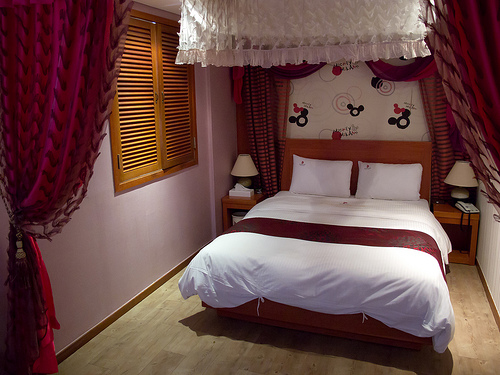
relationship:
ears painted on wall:
[386, 110, 413, 125] [225, 52, 476, 262]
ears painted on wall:
[287, 107, 312, 122] [225, 52, 476, 262]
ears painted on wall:
[344, 100, 364, 110] [225, 52, 476, 262]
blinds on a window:
[116, 18, 192, 178] [71, 14, 229, 235]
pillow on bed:
[293, 155, 351, 196] [152, 134, 466, 375]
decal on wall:
[348, 99, 365, 116] [108, 212, 198, 246]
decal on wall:
[287, 102, 312, 127] [244, 61, 471, 144]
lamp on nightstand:
[443, 160, 480, 201] [429, 201, 483, 265]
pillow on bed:
[354, 160, 423, 200] [179, 137, 447, 362]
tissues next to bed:
[225, 184, 260, 202] [179, 137, 447, 362]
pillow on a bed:
[289, 155, 355, 196] [185, 134, 467, 358]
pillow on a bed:
[349, 151, 436, 202] [248, 186, 483, 336]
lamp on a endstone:
[437, 156, 482, 201] [444, 208, 481, 268]